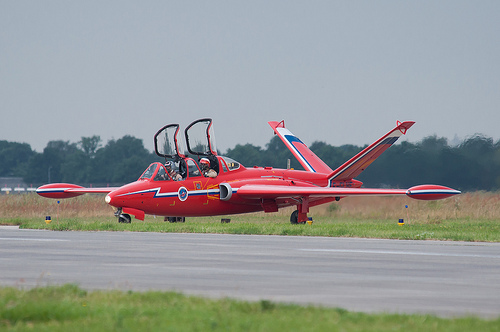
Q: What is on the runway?
A: A plane.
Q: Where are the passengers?
A: In the plane.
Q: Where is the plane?
A: On the grass.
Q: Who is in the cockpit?
A: The pilot.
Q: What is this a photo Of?
A: A jet on an airstrip.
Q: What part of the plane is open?
A: The hatch.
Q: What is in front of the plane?
A: A paved landing strip.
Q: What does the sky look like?
A: Grey and hazy.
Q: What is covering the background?
A: Trees.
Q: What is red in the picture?
A: A plane.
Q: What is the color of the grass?
A: Green.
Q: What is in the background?
A: It's trees.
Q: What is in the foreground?
A: A grass strip.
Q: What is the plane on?
A: It's grass.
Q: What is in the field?
A: A plane.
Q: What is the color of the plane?
A: It's red.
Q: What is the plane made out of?
A: It's metal.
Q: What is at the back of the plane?
A: A plane tail.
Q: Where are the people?
A: Cockpit.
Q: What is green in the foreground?
A: Grass.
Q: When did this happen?
A: During the day.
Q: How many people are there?
A: 2.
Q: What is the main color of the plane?
A: Red.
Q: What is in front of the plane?
A: A runway.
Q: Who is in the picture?
A: Pilots.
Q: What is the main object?
A: A plane.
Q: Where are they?
A: At an airport.